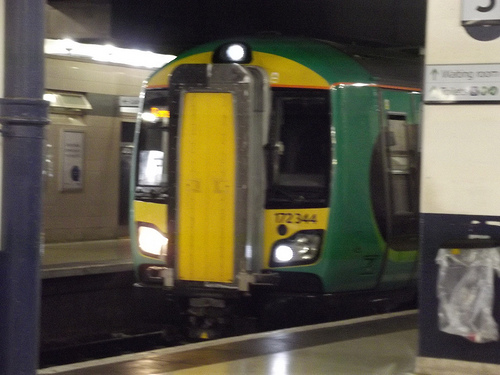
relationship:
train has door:
[125, 27, 420, 343] [171, 89, 243, 291]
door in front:
[171, 89, 243, 291] [128, 31, 391, 345]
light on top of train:
[222, 41, 251, 65] [125, 27, 420, 343]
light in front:
[222, 41, 251, 65] [128, 31, 391, 345]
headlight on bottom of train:
[129, 222, 172, 258] [125, 27, 420, 343]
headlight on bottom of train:
[274, 243, 294, 261] [125, 27, 420, 343]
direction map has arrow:
[423, 60, 497, 104] [429, 66, 441, 83]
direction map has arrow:
[421, 60, 498, 109] [429, 66, 441, 83]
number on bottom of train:
[269, 211, 297, 228] [125, 27, 420, 343]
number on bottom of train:
[294, 211, 320, 228] [125, 27, 420, 343]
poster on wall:
[56, 126, 89, 194] [41, 40, 161, 293]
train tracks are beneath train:
[34, 319, 194, 374] [125, 27, 420, 343]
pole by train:
[1, 1, 54, 374] [125, 27, 420, 343]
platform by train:
[38, 311, 420, 372] [125, 27, 420, 343]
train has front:
[125, 27, 420, 343] [128, 31, 391, 345]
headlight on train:
[265, 224, 330, 273] [125, 27, 420, 343]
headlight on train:
[129, 218, 172, 265] [125, 27, 420, 343]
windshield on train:
[131, 89, 176, 197] [125, 27, 420, 343]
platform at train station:
[38, 311, 420, 372] [0, 1, 499, 374]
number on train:
[269, 211, 297, 228] [125, 27, 420, 343]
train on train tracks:
[125, 27, 420, 343] [34, 319, 194, 374]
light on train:
[222, 41, 251, 65] [125, 27, 420, 343]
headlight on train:
[129, 222, 172, 258] [125, 27, 420, 343]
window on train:
[382, 113, 418, 221] [125, 27, 420, 343]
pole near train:
[1, 1, 54, 374] [125, 27, 420, 343]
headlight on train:
[274, 243, 294, 261] [125, 27, 420, 343]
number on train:
[294, 211, 320, 228] [125, 27, 420, 343]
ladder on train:
[370, 228, 418, 301] [125, 27, 420, 343]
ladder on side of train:
[370, 228, 418, 301] [125, 27, 420, 343]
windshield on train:
[267, 86, 332, 194] [125, 27, 420, 343]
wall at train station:
[41, 40, 161, 293] [0, 1, 499, 374]